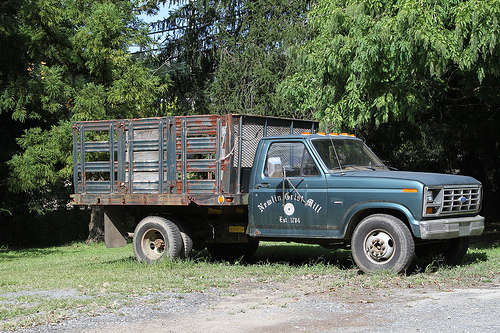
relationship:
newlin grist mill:
[256, 192, 284, 214] [304, 198, 322, 216]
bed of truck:
[65, 110, 321, 218] [67, 110, 487, 284]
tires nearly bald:
[131, 213, 416, 280] [349, 212, 419, 273]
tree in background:
[2, 0, 140, 243] [3, 0, 500, 259]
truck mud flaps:
[67, 110, 487, 284] [101, 205, 144, 251]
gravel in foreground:
[2, 275, 227, 333] [1, 245, 499, 332]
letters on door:
[255, 191, 323, 228] [249, 133, 332, 242]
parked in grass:
[71, 112, 487, 287] [3, 214, 499, 309]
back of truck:
[70, 112, 320, 214] [67, 110, 487, 284]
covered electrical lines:
[53, 0, 354, 98] [118, 8, 282, 77]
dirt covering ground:
[135, 273, 499, 332] [1, 218, 499, 329]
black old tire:
[369, 222, 382, 229] [349, 212, 418, 279]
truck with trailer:
[67, 110, 487, 284] [68, 112, 321, 212]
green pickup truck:
[349, 179, 388, 188] [67, 110, 487, 284]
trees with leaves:
[2, 1, 499, 240] [1, 0, 499, 214]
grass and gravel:
[3, 214, 499, 309] [2, 275, 227, 333]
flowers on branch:
[25, 56, 51, 85] [7, 42, 81, 102]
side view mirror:
[265, 154, 309, 210] [265, 154, 287, 181]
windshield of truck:
[307, 131, 392, 179] [67, 110, 487, 284]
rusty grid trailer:
[167, 114, 234, 208] [68, 112, 321, 212]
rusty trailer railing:
[167, 114, 234, 208] [172, 117, 235, 137]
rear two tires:
[67, 116, 249, 269] [130, 213, 197, 270]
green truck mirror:
[349, 179, 388, 188] [265, 154, 287, 181]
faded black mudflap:
[104, 207, 130, 252] [99, 209, 131, 252]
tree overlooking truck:
[275, 2, 499, 201] [67, 110, 487, 284]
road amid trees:
[4, 267, 498, 333] [2, 1, 499, 240]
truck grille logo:
[67, 110, 487, 284] [456, 196, 470, 205]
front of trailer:
[222, 114, 320, 209] [68, 112, 321, 212]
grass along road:
[3, 214, 499, 309] [4, 267, 498, 333]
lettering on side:
[255, 190, 324, 225] [247, 133, 340, 239]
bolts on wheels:
[368, 239, 386, 257] [130, 211, 417, 280]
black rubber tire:
[369, 222, 382, 229] [349, 212, 418, 279]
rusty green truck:
[167, 114, 234, 208] [67, 110, 487, 284]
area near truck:
[1, 278, 499, 333] [67, 110, 487, 284]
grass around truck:
[3, 214, 499, 309] [67, 110, 487, 284]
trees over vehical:
[2, 1, 499, 240] [67, 110, 487, 284]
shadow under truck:
[183, 238, 490, 275] [67, 110, 487, 284]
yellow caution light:
[302, 131, 312, 136] [302, 129, 359, 141]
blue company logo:
[457, 195, 467, 206] [456, 196, 470, 205]